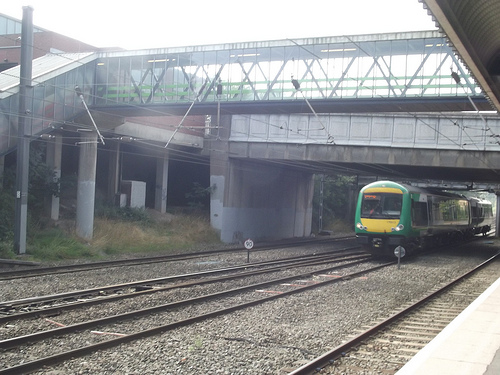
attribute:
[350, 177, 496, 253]
train — green, yellow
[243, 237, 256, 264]
sign — round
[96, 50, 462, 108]
walkway — lit, glass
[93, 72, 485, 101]
railing — green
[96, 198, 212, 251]
hillside — grassy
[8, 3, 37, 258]
metal — tall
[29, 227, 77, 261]
ground — green, grassy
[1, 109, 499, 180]
hanging wires — grey